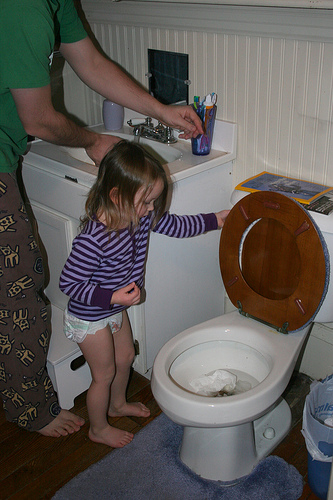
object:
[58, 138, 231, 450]
child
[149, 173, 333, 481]
toilet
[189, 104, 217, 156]
glass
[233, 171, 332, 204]
magazine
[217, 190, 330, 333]
toilet seat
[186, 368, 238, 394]
toilet paper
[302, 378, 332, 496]
wastebasket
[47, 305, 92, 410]
step stool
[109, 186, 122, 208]
ear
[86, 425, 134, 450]
foot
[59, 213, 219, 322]
shirt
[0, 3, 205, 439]
man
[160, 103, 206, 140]
hand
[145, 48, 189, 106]
mirror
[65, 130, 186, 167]
sink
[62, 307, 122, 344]
diaper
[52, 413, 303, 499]
rug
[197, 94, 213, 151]
toothpaste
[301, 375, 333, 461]
trash bag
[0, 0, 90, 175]
shirt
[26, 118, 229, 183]
counter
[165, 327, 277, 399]
toilet bowl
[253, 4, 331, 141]
wall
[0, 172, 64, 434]
pajama bottoms